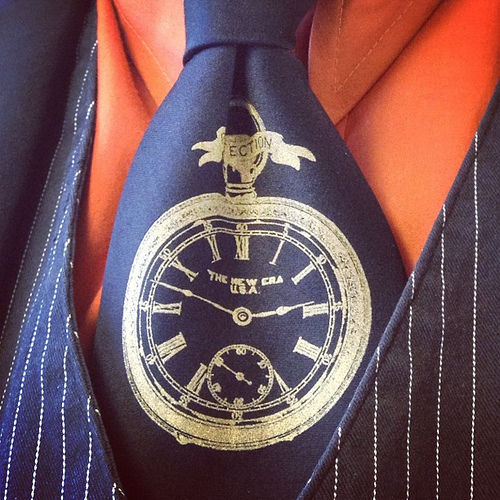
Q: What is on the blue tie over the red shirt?
A: Associatio emblem.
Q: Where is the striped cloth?
A: Vest.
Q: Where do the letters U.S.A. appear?
A: Symbol on tie.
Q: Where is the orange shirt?
A: Behind the blue tie.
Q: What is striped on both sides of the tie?
A: Shirt or vest.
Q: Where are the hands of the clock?
A: Printed emblem.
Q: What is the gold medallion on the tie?
A: Clock.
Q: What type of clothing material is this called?
A: Pin striped.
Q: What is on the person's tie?
A: A clock.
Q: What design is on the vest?
A: Stripes.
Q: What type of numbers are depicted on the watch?
A: Roman numerals.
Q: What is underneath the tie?
A: An orange button up shirt.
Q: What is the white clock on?
A: A tie.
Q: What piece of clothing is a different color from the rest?
A: The orange button up shirt.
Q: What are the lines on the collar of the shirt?
A: Stitching.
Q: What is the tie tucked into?
A: A vest.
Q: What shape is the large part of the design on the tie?
A: Circle.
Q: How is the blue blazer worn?
A: Over a vest.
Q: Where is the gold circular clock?
A: On a tie.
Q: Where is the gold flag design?
A: On the tie.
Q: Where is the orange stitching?
A: On the orange shirt.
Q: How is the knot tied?
A: Traditional style.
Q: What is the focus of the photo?
A: A suited individual with tie and vest.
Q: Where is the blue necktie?
A: Under the striped suit.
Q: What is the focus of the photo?
A: Orange shirt and blue tie.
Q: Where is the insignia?
A: On a necktie.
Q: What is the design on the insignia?
A: A pocket watch.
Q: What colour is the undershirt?
A: Peach.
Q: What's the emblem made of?
A: Gold.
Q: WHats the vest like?
A: Pinstripes.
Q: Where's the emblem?
A: On tie.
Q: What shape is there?
A: Circle.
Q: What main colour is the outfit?
A: Blue.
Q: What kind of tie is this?
A: Neck tie.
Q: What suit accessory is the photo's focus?
A: Tie.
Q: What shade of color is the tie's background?
A: Blue.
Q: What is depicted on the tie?
A: A clock face.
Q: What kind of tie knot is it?
A: A four-in-hand.